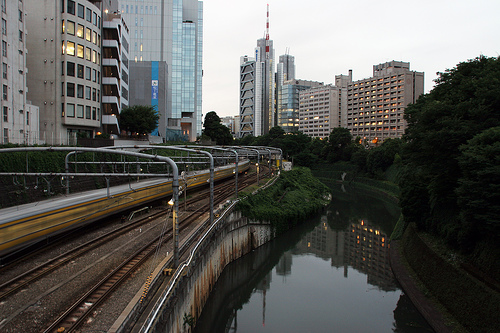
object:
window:
[65, 42, 78, 56]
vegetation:
[243, 169, 332, 222]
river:
[200, 171, 445, 332]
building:
[0, 0, 46, 155]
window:
[76, 84, 83, 98]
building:
[298, 84, 339, 140]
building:
[253, 0, 279, 138]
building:
[234, 49, 259, 141]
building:
[276, 46, 295, 80]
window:
[282, 102, 289, 109]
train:
[1, 164, 245, 259]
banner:
[149, 60, 158, 137]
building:
[128, 60, 169, 143]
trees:
[393, 52, 499, 233]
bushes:
[451, 128, 500, 264]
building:
[29, 1, 105, 144]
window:
[77, 64, 82, 78]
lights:
[61, 20, 74, 34]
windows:
[192, 108, 201, 115]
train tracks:
[0, 203, 198, 332]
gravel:
[80, 261, 104, 279]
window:
[85, 68, 93, 80]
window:
[67, 103, 75, 118]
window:
[60, 21, 76, 35]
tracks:
[0, 185, 229, 333]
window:
[77, 104, 84, 119]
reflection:
[274, 216, 400, 306]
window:
[74, 24, 86, 39]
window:
[184, 20, 191, 30]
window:
[189, 51, 194, 57]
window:
[179, 65, 183, 70]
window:
[171, 78, 178, 84]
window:
[179, 85, 188, 98]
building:
[126, 0, 206, 136]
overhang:
[0, 142, 183, 275]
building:
[346, 59, 424, 148]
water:
[238, 254, 474, 332]